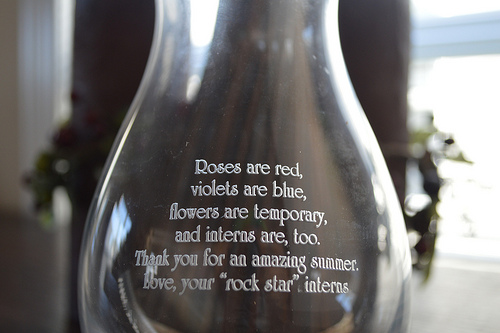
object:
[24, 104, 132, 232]
plant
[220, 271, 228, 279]
quotation marks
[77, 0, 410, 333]
reflection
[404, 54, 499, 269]
window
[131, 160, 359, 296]
etched poem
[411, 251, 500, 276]
sill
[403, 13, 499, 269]
frame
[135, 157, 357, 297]
writing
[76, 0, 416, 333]
vase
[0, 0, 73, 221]
blinds